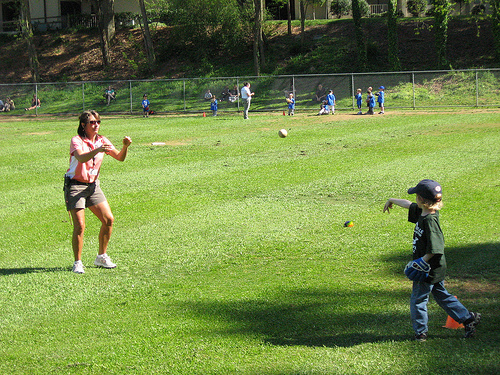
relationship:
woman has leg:
[60, 109, 135, 275] [89, 189, 116, 269]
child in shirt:
[378, 85, 383, 110] [377, 90, 386, 101]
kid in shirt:
[354, 88, 363, 115] [355, 94, 364, 104]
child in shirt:
[328, 87, 337, 113] [329, 94, 336, 103]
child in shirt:
[209, 96, 224, 111] [210, 101, 218, 110]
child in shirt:
[284, 94, 295, 114] [287, 96, 298, 109]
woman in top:
[240, 82, 257, 116] [239, 87, 251, 99]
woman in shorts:
[60, 109, 135, 275] [66, 176, 107, 211]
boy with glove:
[379, 176, 487, 345] [405, 257, 431, 286]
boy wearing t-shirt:
[379, 176, 487, 345] [408, 200, 449, 286]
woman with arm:
[60, 109, 135, 275] [69, 139, 110, 165]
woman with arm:
[60, 109, 135, 275] [101, 134, 134, 164]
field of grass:
[2, 112, 498, 374] [1, 82, 497, 371]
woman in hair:
[60, 109, 135, 275] [71, 109, 106, 144]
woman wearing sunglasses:
[60, 109, 135, 275] [76, 111, 106, 133]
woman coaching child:
[240, 81, 255, 119] [375, 86, 386, 115]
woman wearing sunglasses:
[60, 109, 135, 275] [83, 117, 102, 127]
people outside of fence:
[1, 81, 47, 123] [431, 81, 496, 107]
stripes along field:
[1, 117, 455, 218] [2, 112, 498, 374]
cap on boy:
[398, 180, 448, 197] [383, 181, 438, 273]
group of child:
[277, 65, 399, 123] [375, 86, 386, 115]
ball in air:
[265, 111, 301, 163] [154, 44, 356, 197]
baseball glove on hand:
[402, 257, 430, 283] [382, 198, 394, 213]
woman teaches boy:
[60, 109, 135, 275] [379, 176, 487, 345]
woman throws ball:
[60, 109, 135, 275] [276, 125, 290, 138]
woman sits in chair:
[101, 83, 121, 107] [99, 97, 117, 102]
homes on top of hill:
[0, 0, 495, 37] [0, 25, 494, 105]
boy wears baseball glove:
[379, 176, 487, 345] [402, 257, 431, 283]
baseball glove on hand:
[402, 257, 431, 283] [400, 257, 430, 284]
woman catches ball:
[60, 109, 135, 275] [268, 116, 296, 148]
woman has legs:
[38, 95, 133, 271] [331, 238, 482, 345]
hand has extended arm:
[383, 199, 391, 216] [389, 196, 419, 218]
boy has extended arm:
[382, 178, 481, 343] [389, 196, 419, 218]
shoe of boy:
[463, 310, 480, 330] [382, 178, 481, 343]